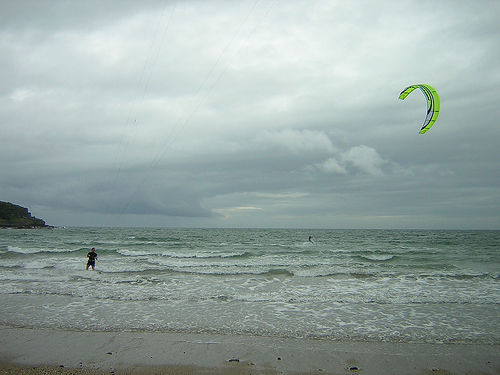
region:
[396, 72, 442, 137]
a bright green kite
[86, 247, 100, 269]
a man flying a kite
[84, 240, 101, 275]
a man standing in the surf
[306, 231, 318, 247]
a person surfing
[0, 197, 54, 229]
a tip of land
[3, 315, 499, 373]
wet sand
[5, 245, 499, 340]
ocean waves at the shore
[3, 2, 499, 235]
a cloudy sky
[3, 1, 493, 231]
a green kite is in the sky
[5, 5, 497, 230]
there are no birds in the sky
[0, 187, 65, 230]
rocky outcropping extending to the sea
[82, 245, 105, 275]
man standing in ocean waves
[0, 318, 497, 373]
shoreline with light brown sand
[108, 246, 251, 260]
white-caps crashing downwards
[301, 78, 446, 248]
man riding waves via para-sail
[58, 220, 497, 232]
horizon above the ocean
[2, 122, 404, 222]
dark foreboding clouds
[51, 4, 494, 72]
lighter fluffy clouds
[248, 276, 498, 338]
white frothy foam washing up on shore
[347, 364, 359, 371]
small rock on beach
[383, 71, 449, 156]
parachute is green in color.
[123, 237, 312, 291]
water has waves.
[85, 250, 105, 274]
man is wearing black dress.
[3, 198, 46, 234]
a small foothill is on left side of the picture.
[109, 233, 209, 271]
water is blue in color.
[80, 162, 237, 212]
sky is grey.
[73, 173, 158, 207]
day is cloudy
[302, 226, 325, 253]
man is surfing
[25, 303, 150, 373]
sand is wet due to water.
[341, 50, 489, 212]
parachute is flying in the sky.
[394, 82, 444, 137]
green parasail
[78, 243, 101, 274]
man in the ocean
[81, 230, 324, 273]
two people in the ocean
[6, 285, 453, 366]
beach at the ocean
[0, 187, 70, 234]
rocky landscape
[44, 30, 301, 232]
cloudy day at the ocean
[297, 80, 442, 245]
man windsurfing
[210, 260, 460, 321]
ocean waves rolling in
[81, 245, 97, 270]
man wearing black standing in the ocean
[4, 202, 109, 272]
man in front of a rocky cliff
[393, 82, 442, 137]
a green kite flying in the air.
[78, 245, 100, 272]
a man standing in the water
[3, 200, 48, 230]
a hill by the ocean.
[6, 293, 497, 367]
an empty beach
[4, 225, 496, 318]
the ocean with two people in it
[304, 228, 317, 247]
someone surfing in the water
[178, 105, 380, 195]
grey clouds in the sky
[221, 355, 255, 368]
seaweed on the sand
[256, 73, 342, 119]
sun trying to break through the clouds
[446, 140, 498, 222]
dark grey clouds